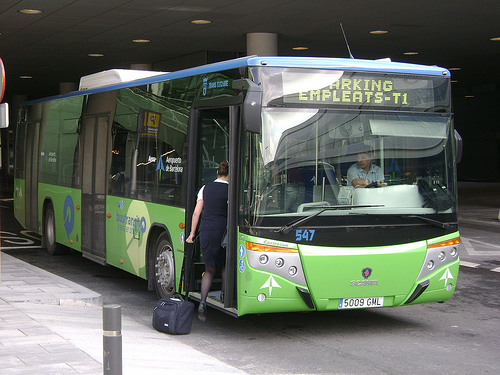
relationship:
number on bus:
[296, 229, 316, 241] [201, 36, 472, 328]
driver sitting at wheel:
[341, 143, 379, 188] [363, 169, 388, 179]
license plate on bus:
[341, 297, 385, 308] [5, 50, 462, 327]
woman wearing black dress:
[185, 160, 229, 321] [194, 179, 239, 272]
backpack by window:
[413, 175, 452, 214] [267, 107, 444, 224]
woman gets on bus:
[185, 160, 229, 321] [17, 53, 494, 328]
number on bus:
[296, 228, 316, 243] [5, 50, 462, 327]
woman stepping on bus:
[185, 160, 229, 321] [11, 23, 465, 318]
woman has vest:
[179, 161, 239, 329] [203, 178, 232, 241]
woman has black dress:
[185, 160, 229, 321] [197, 179, 229, 269]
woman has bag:
[185, 160, 229, 321] [141, 293, 201, 345]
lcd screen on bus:
[294, 72, 412, 111] [5, 50, 462, 327]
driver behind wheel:
[347, 145, 388, 188] [365, 176, 390, 187]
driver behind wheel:
[347, 145, 388, 188] [358, 179, 386, 192]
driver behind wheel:
[347, 145, 388, 188] [354, 177, 394, 193]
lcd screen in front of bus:
[299, 77, 409, 105] [5, 50, 462, 327]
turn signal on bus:
[245, 238, 300, 257] [11, 23, 465, 318]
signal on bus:
[428, 231, 459, 262] [114, 86, 499, 271]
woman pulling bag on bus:
[185, 160, 229, 321] [5, 50, 462, 327]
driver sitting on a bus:
[347, 145, 388, 188] [32, 74, 322, 203]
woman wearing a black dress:
[185, 160, 229, 321] [197, 179, 229, 269]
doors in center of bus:
[75, 107, 110, 264] [5, 50, 462, 327]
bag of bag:
[155, 234, 199, 352] [152, 294, 196, 335]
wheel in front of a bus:
[145, 236, 199, 331] [132, 223, 178, 302]